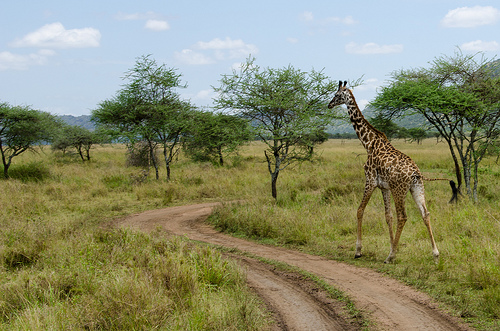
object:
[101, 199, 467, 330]
road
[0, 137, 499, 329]
field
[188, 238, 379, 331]
median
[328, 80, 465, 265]
giraffe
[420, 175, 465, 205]
tail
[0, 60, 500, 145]
mountains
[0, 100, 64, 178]
trees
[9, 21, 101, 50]
cloud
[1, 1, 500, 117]
sky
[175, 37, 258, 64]
cloud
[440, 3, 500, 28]
cloud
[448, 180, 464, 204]
hair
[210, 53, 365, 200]
tree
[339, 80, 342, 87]
horns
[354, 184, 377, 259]
leg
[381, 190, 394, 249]
leg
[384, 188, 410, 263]
leg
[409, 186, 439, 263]
leg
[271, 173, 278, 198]
trunk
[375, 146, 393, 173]
spots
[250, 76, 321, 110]
leaves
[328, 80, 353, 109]
head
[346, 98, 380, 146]
neck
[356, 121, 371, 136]
spots